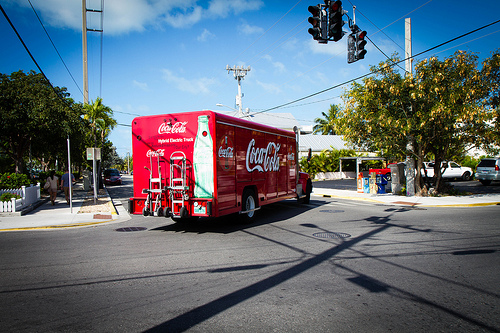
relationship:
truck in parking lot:
[415, 158, 473, 182] [312, 174, 497, 198]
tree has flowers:
[315, 51, 499, 194] [321, 48, 498, 148]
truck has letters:
[129, 108, 313, 227] [242, 136, 282, 172]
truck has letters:
[129, 108, 313, 227] [157, 118, 189, 136]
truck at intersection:
[129, 108, 313, 227] [95, 201, 429, 257]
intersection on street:
[95, 201, 429, 257] [3, 170, 494, 327]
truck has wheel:
[129, 108, 313, 227] [242, 190, 258, 221]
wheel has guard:
[242, 190, 258, 221] [239, 206, 260, 214]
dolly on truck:
[143, 149, 163, 218] [129, 108, 313, 227]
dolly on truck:
[168, 148, 187, 218] [129, 108, 313, 227]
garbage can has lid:
[81, 176, 93, 192] [83, 175, 90, 179]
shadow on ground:
[144, 212, 421, 329] [18, 218, 496, 328]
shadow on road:
[144, 212, 421, 329] [3, 170, 494, 327]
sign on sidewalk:
[87, 146, 100, 161] [6, 174, 103, 228]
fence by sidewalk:
[2, 181, 42, 216] [6, 174, 103, 228]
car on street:
[105, 168, 124, 187] [3, 170, 494, 327]